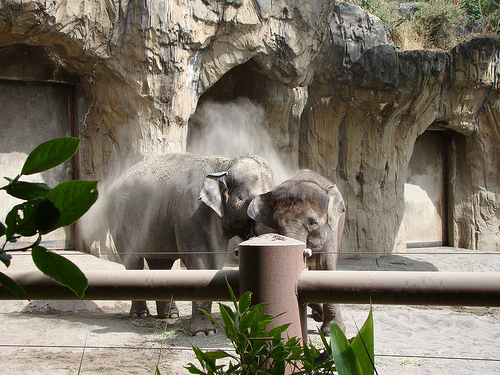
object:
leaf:
[21, 136, 81, 176]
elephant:
[102, 152, 277, 338]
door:
[404, 128, 446, 249]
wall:
[10, 2, 498, 254]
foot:
[183, 313, 217, 338]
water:
[188, 95, 290, 184]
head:
[196, 153, 279, 237]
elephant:
[247, 167, 347, 336]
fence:
[0, 234, 499, 375]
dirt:
[240, 231, 305, 245]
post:
[239, 232, 314, 375]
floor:
[0, 310, 192, 374]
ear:
[197, 170, 232, 218]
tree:
[182, 282, 383, 374]